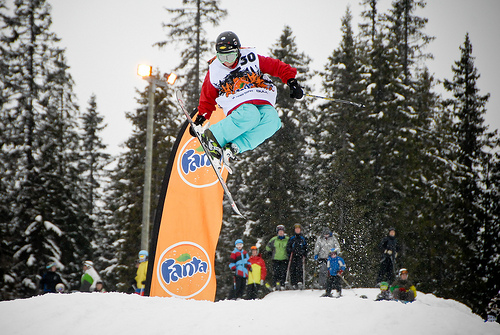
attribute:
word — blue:
[181, 150, 218, 172]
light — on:
[137, 62, 153, 78]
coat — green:
[266, 236, 289, 260]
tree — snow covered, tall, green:
[427, 30, 500, 323]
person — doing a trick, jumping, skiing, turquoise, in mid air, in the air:
[189, 33, 304, 164]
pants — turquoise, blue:
[208, 104, 283, 154]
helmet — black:
[213, 31, 241, 51]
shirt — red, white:
[193, 53, 295, 120]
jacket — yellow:
[136, 262, 149, 288]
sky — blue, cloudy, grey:
[1, 2, 500, 211]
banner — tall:
[149, 101, 232, 301]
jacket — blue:
[324, 255, 348, 277]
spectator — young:
[324, 250, 348, 298]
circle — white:
[177, 136, 226, 188]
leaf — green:
[196, 145, 205, 154]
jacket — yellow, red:
[245, 256, 269, 284]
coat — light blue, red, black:
[228, 250, 250, 277]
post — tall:
[132, 59, 179, 297]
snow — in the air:
[308, 224, 368, 286]